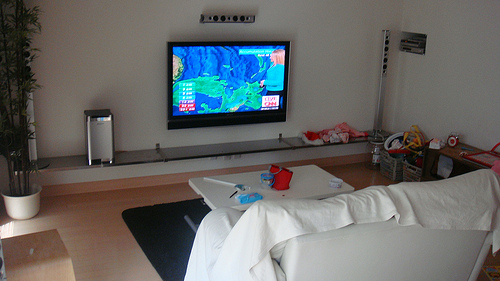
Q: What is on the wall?
A: A flat screen tv on the wall.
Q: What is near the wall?
A: A plant.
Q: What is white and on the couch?
A: A cover on the couch.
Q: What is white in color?
A: A recliner chair.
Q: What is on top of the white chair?
A: A white blanket.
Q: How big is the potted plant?
A: The potted plant is very tall.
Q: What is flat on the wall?
A: The screen TV.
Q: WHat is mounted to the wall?
A: A TV.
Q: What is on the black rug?
A: A white table.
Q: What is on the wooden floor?
A: A black rug.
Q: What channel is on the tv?
A: CNN.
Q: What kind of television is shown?
A: A flat screen.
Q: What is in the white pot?
A: A plant.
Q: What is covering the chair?
A: A white cover.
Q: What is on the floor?
A: A black rug.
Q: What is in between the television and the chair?
A: A table.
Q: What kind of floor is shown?
A: Wood.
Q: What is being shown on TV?
A: The weather.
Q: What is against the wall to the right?
A: Cartons.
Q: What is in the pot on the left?
A: A plant.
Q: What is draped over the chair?
A: A white sheet.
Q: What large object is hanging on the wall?
A: A television.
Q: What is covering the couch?
A: A cover.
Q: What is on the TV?
A: The weather.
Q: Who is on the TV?
A: Weather forecaster.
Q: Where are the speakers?
A: Above and beside the TV.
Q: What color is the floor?
A: Tan.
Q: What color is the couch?
A: White.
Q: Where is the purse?
A: On the table.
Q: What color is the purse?
A: Red.